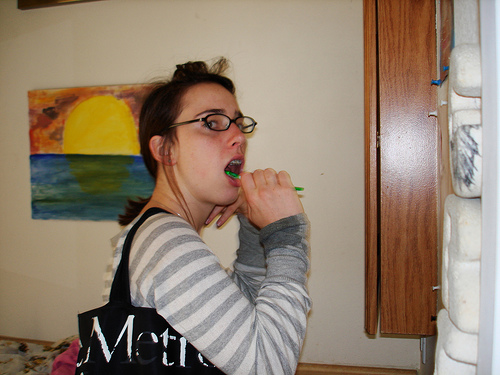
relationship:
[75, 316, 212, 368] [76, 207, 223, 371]
letters on bag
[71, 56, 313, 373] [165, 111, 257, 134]
girl wears glasses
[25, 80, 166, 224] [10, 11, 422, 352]
painting on wall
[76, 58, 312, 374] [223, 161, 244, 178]
girl brush teeth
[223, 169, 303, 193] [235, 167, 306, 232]
toothbrush in hand